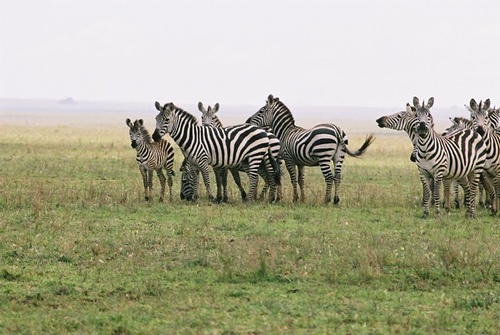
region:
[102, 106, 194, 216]
Small black and white zebra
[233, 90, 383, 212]
Large black and white zebra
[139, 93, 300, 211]
Large black and white zebra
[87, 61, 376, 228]
Group of black and white zebras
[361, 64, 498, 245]
Group of black and white zebras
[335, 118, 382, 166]
Furry zebra tail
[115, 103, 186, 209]
Baby black and white zebra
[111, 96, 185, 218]
Young black and white zebra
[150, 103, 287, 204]
Medium sized adult zebra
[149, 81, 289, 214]
Fully grown adult zebra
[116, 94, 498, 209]
a group of at least eight zebras stand on the grass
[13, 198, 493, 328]
grass is green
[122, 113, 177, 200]
smallest zebra in the group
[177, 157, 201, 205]
zebra eating grass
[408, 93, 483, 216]
zebra faces the camera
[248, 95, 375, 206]
zebra faces away from camera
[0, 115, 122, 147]
yellow grass in the distance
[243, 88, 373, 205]
zebra in the middle swishes its tail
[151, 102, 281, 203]
zebra broadside to camera shows all its stripes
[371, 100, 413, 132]
zebra lifts its head to sniff the air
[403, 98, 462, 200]
A zebra stares at the camera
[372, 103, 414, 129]
A zebra looks to the left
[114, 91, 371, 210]
Four zebras in a group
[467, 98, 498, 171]
Another zebra stares at the camera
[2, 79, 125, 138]
Fog covering the area in the distance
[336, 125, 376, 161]
A zebra tail swishes in the air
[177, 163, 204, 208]
A zebra eating grass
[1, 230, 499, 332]
A grassy plain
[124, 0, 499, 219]
A group of zebras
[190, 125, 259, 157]
Black and white stripes on the zebra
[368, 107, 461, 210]
pointy nosed zebra sniffs the air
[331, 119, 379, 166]
zebra's tail is swishing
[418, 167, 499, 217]
many legs of seen & hidden zebras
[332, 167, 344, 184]
grey back of zebra knee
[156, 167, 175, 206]
knobby knees & skinny hind legs of zebra colt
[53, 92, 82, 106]
something ufo-shaped that's probably a hill, house, or earth mound on horizon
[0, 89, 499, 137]
gradated colors of lavender, grey, yellow on the horizon, made from sky+ground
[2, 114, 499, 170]
many yellow grasses in mid-background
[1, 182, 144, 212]
long weeds+grass beside zebra calf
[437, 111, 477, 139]
brushy mane of mostly hidden zebra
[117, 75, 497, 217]
a herd of zebras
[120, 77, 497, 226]
prey for the king of the jungle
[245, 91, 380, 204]
zebra with a tail swish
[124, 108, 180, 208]
a young zebra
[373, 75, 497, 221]
a couple of zebras notice the photographer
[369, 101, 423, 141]
a zebra is braying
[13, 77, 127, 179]
small hills in the background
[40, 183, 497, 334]
short grass from grazing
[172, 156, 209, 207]
a grazing zebra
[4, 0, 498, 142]
a hazy sky